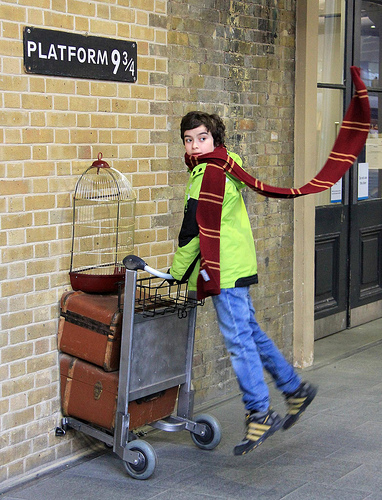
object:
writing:
[28, 40, 108, 66]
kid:
[165, 110, 317, 455]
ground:
[4, 318, 379, 498]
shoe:
[277, 380, 321, 432]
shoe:
[231, 404, 285, 458]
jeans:
[208, 278, 314, 422]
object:
[116, 436, 158, 481]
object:
[60, 258, 232, 483]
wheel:
[121, 438, 159, 482]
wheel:
[187, 414, 222, 452]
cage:
[67, 151, 142, 294]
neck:
[184, 153, 221, 167]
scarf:
[181, 65, 371, 303]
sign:
[21, 24, 138, 84]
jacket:
[165, 149, 264, 294]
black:
[184, 218, 195, 235]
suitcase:
[58, 290, 129, 372]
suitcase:
[53, 351, 183, 437]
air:
[0, 9, 380, 497]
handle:
[120, 254, 193, 281]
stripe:
[330, 152, 355, 158]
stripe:
[340, 115, 372, 127]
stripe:
[257, 181, 269, 192]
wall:
[0, 1, 306, 491]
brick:
[111, 94, 140, 115]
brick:
[148, 69, 175, 87]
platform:
[6, 5, 378, 499]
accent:
[176, 197, 204, 250]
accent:
[173, 245, 207, 285]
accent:
[233, 272, 262, 289]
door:
[312, 0, 350, 351]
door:
[346, 4, 380, 329]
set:
[314, 3, 380, 350]